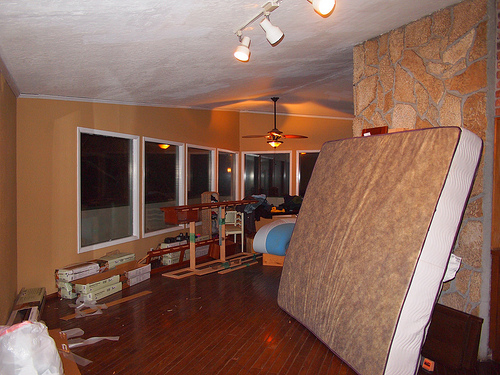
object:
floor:
[128, 338, 358, 374]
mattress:
[275, 126, 484, 375]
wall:
[351, 0, 499, 363]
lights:
[233, 36, 250, 63]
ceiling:
[0, 0, 474, 118]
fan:
[240, 96, 308, 150]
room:
[0, 0, 499, 374]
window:
[74, 126, 140, 255]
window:
[140, 135, 186, 239]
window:
[184, 142, 215, 206]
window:
[216, 149, 238, 204]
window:
[239, 150, 291, 201]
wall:
[0, 58, 354, 328]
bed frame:
[420, 303, 483, 373]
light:
[267, 142, 283, 148]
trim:
[77, 126, 140, 254]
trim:
[140, 136, 185, 239]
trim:
[185, 144, 213, 205]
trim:
[216, 148, 238, 202]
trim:
[240, 151, 289, 200]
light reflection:
[157, 142, 171, 151]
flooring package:
[53, 261, 101, 282]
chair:
[224, 211, 244, 253]